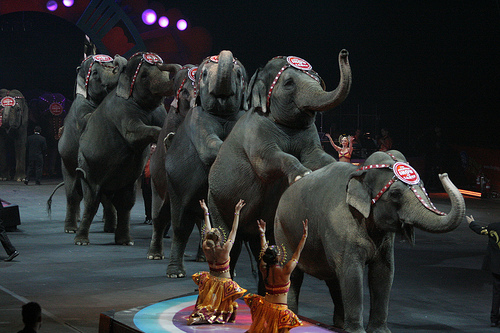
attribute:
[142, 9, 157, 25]
light — bright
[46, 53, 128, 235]
elephant — performing, gray, grey, here, standing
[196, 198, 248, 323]
woman — here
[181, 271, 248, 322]
skirt — gold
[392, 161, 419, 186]
circle — red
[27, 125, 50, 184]
man — standing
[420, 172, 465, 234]
tusk — curled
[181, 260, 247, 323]
costume — yellow